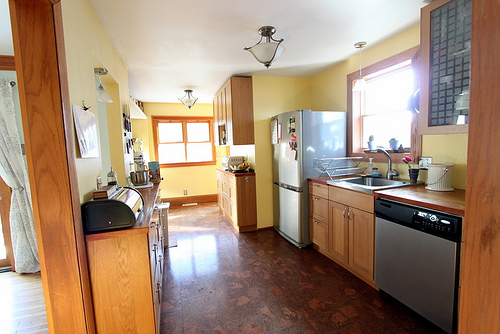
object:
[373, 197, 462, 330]
dishwasher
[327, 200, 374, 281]
cabinet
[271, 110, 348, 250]
refrigerator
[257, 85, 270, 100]
wall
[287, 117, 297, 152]
magnets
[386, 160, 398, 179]
faucet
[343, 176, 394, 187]
sink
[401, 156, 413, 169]
flower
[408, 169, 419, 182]
vase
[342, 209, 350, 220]
handles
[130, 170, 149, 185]
bowl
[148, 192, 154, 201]
counter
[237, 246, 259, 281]
floor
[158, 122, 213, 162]
window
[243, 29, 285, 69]
light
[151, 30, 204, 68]
ceiling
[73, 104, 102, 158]
picture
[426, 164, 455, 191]
pot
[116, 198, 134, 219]
breadbox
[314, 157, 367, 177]
rack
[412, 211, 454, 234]
buttons